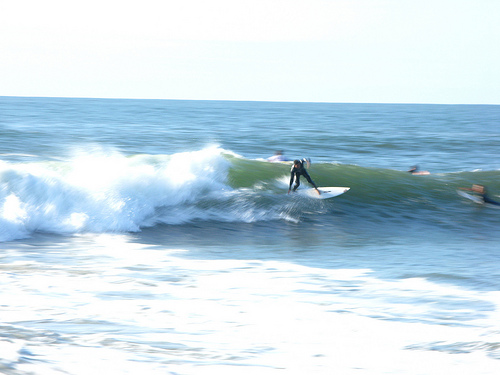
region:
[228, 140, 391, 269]
a surfer riding a wave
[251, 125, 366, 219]
surfer wearing a black wetsuit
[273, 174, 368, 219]
a white surboard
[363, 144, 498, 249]
other surfers in the background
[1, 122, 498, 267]
a wave break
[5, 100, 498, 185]
the calm ocean behind the wave break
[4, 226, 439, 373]
sea foam from a previous wave in the foreground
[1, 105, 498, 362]
one surfer rides a wave with three other surfers in the picture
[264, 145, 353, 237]
a surfer bending down while riding a wave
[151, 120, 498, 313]
the ocean water looks green in the wave and blue elsewhere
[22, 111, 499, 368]
a sunny day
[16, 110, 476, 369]
the ocean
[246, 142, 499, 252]
people in the water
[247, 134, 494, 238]
surfers in the ocean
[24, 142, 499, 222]
a wave on the water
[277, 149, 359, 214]
the surfer is wearing a wetsuit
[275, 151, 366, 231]
the person on the surfboard is wearing black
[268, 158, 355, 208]
the surfboard is white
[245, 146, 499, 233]
four people are in the water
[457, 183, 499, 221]
a person paddles towards the wave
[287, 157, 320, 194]
a surfer on wave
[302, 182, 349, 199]
man's leg on surfboard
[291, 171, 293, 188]
arm holding the surfboard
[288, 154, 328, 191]
man wearing wetsuit in water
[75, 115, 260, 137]
back portion of the water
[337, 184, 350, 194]
the tip of the surfboard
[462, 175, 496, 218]
an object in the water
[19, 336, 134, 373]
portion of water in front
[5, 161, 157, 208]
portion of foamy wave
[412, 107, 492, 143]
portion of calmer waters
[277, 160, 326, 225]
Surfer in the middle of a wave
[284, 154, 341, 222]
Surfer standing on top of surf board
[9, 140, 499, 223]
Wave for surfing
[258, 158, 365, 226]
Surfer wearing a body suit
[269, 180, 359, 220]
White surfboard with person standing on top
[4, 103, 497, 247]
Wave in the middle of the ocean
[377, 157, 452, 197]
Person trying to surf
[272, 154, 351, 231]
Person leaning on a surfboard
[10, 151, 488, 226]
Person going across a wave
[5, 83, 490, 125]
Horizon line of the ocean and sky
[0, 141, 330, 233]
the wave is cresting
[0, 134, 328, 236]
white mist on top of a wave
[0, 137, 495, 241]
a wave in the ocean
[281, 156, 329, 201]
a surfer in a black wetsuit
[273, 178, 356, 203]
a white surfboard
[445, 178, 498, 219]
a person swimming in the wave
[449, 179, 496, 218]
a person laying flat on a surfboard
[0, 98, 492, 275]
blue water all around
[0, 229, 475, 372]
white foam on the ocean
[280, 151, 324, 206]
a person keeping their balance